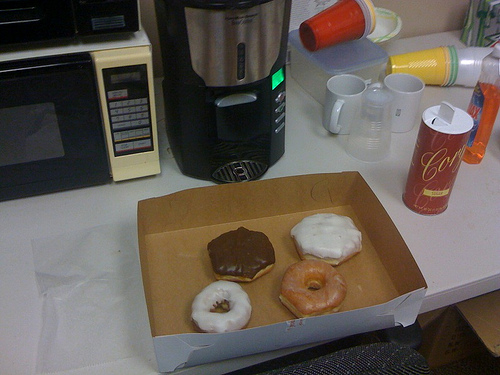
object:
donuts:
[191, 212, 363, 333]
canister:
[400, 103, 475, 215]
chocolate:
[207, 226, 275, 277]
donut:
[205, 225, 276, 282]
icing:
[291, 211, 362, 257]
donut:
[291, 213, 362, 263]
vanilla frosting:
[191, 280, 249, 331]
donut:
[191, 281, 251, 334]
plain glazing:
[281, 261, 347, 314]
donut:
[277, 258, 348, 317]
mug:
[325, 73, 367, 136]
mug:
[378, 73, 426, 134]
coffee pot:
[160, 0, 295, 183]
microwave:
[0, 38, 158, 203]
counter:
[0, 31, 499, 373]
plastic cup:
[300, 0, 372, 51]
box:
[135, 171, 430, 374]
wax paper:
[38, 232, 146, 374]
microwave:
[1, 3, 142, 50]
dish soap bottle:
[458, 44, 499, 167]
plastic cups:
[343, 92, 394, 162]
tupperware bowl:
[287, 28, 390, 107]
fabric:
[250, 339, 428, 375]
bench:
[253, 340, 436, 375]